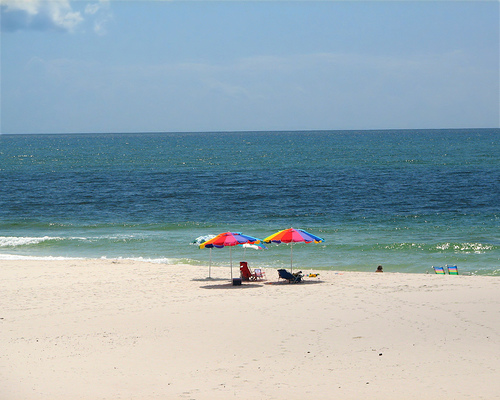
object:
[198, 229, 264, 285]
beach umbrellas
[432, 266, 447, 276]
beach chairs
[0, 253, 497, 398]
beach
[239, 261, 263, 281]
chairs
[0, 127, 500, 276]
ocean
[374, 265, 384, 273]
person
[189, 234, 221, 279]
umbrella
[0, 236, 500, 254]
wave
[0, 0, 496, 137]
sky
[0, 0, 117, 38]
clouds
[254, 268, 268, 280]
chair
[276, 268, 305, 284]
black chair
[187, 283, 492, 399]
footprints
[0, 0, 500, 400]
picture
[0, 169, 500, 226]
water section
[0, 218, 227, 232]
waves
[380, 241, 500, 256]
ripples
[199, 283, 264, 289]
shadows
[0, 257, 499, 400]
sand